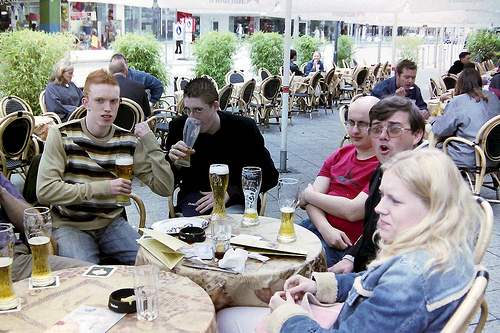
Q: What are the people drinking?
A: Beer.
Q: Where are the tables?
A: On the sidewalk.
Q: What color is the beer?
A: Gold.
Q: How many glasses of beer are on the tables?
A: 5.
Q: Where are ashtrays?
A: On the tables.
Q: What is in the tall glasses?
A: Beer.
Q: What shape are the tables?
A: Round.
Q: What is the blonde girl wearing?
A: Blue jacket.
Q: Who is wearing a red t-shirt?
A: The bald man.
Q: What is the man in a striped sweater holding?
A: Beer glass.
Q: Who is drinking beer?
A: Young man in a black shirt.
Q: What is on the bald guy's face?
A: Eyeglasses.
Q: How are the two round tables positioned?
A: Next to each other.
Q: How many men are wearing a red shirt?
A: One.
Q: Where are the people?
A: Seated at a table.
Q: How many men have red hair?
A: One.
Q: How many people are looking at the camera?
A: One.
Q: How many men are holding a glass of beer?
A: Two.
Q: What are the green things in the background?
A: Bushes.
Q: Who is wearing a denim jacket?
A: Woman with blond hair.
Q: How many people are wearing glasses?
A: One.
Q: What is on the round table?
A: Drinks and menus.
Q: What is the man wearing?
A: A black jacket.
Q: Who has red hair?
A: The man on the left.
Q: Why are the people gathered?
A: To drink.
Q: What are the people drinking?
A: Beer.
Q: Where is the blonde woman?
A: Right.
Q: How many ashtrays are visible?
A: Two.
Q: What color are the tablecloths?
A: Brown.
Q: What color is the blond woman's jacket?
A: Blue.